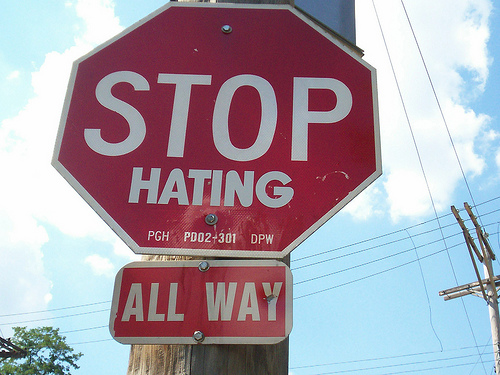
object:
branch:
[45, 323, 79, 366]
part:
[222, 168, 255, 208]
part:
[211, 343, 287, 373]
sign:
[49, 1, 384, 345]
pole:
[125, 343, 290, 374]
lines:
[399, 0, 487, 234]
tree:
[0, 322, 85, 373]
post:
[435, 199, 499, 374]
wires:
[1, 303, 81, 319]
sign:
[105, 258, 294, 346]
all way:
[118, 279, 285, 322]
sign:
[48, 0, 385, 259]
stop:
[81, 68, 355, 162]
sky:
[0, 0, 499, 374]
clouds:
[383, 0, 499, 227]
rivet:
[202, 212, 220, 226]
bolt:
[219, 23, 234, 35]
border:
[164, 0, 366, 55]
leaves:
[12, 326, 26, 336]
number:
[216, 230, 238, 244]